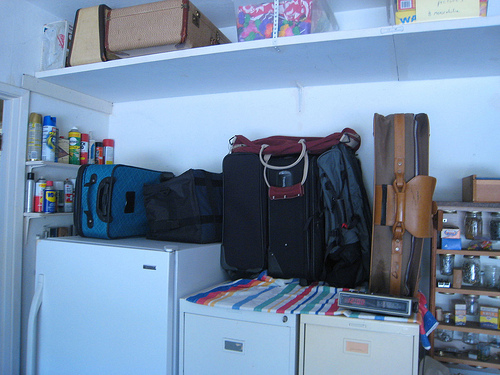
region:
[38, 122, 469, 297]
suitcases on the washer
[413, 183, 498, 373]
a shelf with sulppies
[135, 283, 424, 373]
two file cabinets together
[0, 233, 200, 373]
a small white frig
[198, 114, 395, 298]
suit cases with a bag on top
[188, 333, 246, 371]
the handle on the file cabinet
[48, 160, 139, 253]
a black and blue suitcase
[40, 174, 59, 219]
a can of w-d40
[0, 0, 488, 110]
a shelve up above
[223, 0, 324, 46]
a clear tote with closes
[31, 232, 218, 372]
A compact refrigerator.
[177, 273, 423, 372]
Two filing cabinets.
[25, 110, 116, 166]
A shelf full of cans.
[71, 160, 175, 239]
A blue suitcase on a refrigerator.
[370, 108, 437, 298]
A brown suitcase on a file cabinet.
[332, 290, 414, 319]
A clock radio in front of a suitcase.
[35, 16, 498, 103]
A white shelf near a ceiling.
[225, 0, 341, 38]
A box of clothes on a shelf.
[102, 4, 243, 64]
Brown suitcase on a shelf.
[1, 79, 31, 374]
A door frame next to a wall shelf.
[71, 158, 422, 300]
suitcases sitting under a shelf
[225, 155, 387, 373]
suitcases sitting on top of filing cabinet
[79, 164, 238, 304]
suitcases sitting on top of refridgerator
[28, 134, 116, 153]
spray paint cans sitting on a shelf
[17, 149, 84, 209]
a shelf built into a wall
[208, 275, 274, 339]
a blanket laying on top of filing cabinet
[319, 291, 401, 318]
an alarm clock laying on top of cabinet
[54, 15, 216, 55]
a suitcase sitting on a shelf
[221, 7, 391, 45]
storage bin sitting on top of shelf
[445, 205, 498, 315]
small trinckets sitting in a small shelf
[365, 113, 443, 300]
A luggage bag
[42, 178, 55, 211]
Can of WD-40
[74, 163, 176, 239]
A blue luggage bag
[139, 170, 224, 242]
A black tote bag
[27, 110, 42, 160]
Gold can of spraypaint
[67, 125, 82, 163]
A green aerosol can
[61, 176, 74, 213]
A white and red spray can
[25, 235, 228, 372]
A white small refrigerator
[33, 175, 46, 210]
Red and white can of spray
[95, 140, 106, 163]
Black and red can of spray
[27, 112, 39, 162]
can on the shelf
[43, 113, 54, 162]
can on the shelf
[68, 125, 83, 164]
can on the shelf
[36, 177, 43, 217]
can on the shelf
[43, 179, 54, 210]
can on the shelf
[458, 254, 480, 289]
jar on the shelf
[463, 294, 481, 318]
jar on the shelf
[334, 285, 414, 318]
clock on the file cabinet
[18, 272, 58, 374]
handle on the refrigerator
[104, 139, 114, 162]
can on the shelf